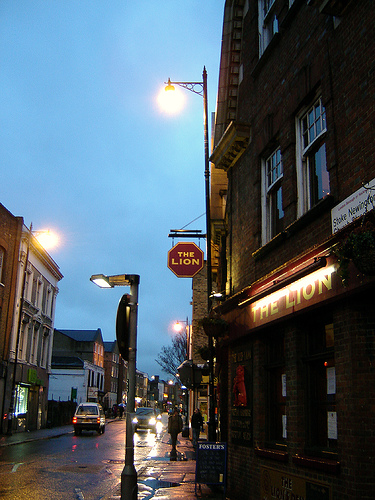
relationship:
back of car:
[72, 401, 101, 429] [69, 398, 107, 435]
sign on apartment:
[325, 176, 374, 242] [206, 0, 373, 499]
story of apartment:
[211, 31, 374, 295] [206, 0, 373, 499]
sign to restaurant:
[236, 265, 343, 329] [191, 215, 373, 496]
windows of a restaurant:
[258, 328, 352, 458] [202, 253, 367, 499]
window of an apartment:
[308, 144, 330, 210] [205, 32, 374, 286]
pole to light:
[122, 285, 146, 498] [88, 263, 150, 496]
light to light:
[86, 266, 145, 305] [88, 263, 150, 496]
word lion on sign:
[282, 268, 335, 314] [231, 265, 330, 337]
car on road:
[70, 400, 106, 438] [0, 415, 169, 498]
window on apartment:
[293, 93, 331, 215] [206, 0, 373, 499]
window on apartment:
[261, 145, 282, 240] [206, 0, 373, 499]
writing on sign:
[195, 445, 224, 450] [195, 440, 226, 475]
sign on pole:
[166, 240, 203, 280] [176, 70, 211, 496]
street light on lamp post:
[150, 82, 193, 121] [201, 64, 215, 441]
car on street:
[70, 400, 106, 438] [2, 415, 158, 498]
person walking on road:
[167, 411, 177, 457] [0, 415, 169, 499]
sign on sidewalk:
[195, 440, 230, 483] [162, 426, 264, 498]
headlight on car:
[143, 416, 156, 428] [130, 407, 158, 433]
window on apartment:
[308, 144, 330, 210] [206, 0, 373, 499]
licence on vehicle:
[80, 418, 94, 424] [75, 401, 107, 432]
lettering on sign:
[197, 441, 222, 451] [195, 441, 226, 484]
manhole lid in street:
[111, 457, 125, 465] [1, 412, 170, 496]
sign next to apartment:
[167, 240, 205, 280] [206, 0, 373, 499]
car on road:
[69, 400, 109, 434] [0, 415, 169, 498]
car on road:
[129, 403, 159, 434] [0, 415, 169, 498]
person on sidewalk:
[166, 406, 183, 458] [119, 432, 205, 498]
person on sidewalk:
[188, 407, 205, 452] [119, 432, 205, 498]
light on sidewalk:
[89, 272, 114, 290] [122, 431, 226, 498]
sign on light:
[112, 291, 132, 363] [89, 272, 114, 290]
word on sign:
[249, 296, 281, 321] [211, 261, 340, 344]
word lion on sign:
[282, 268, 335, 309] [211, 261, 340, 344]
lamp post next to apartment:
[161, 61, 220, 446] [206, 0, 373, 499]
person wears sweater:
[187, 401, 206, 447] [186, 412, 206, 431]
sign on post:
[166, 240, 203, 280] [198, 65, 221, 440]